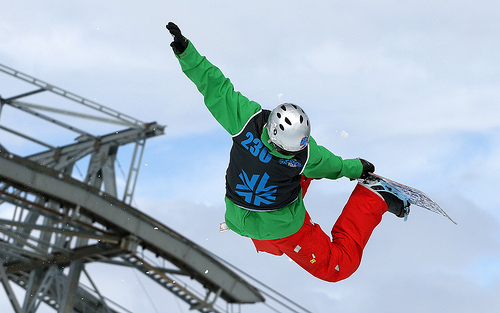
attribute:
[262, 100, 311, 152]
helmet — silver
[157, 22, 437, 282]
snowboarder — athletic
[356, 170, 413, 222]
boot — black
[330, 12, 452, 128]
cloud — white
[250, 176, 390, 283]
snow pants — red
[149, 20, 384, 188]
arms — out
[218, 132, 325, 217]
vest — black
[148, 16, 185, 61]
glove — black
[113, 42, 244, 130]
arm — outstreteched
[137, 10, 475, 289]
snow boarder — airborne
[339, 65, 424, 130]
clouds — white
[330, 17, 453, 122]
sky — blue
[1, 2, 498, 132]
clouds — white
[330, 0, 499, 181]
clouds — white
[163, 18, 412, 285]
person — athletic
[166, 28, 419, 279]
snowboarder — athletic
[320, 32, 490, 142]
clouds — white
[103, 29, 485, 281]
snowboarder — athletic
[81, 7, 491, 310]
sky — blue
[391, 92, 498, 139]
clouds — white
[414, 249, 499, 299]
clouds — white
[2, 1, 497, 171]
cloud — white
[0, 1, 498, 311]
sky — blue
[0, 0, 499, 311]
clouds — white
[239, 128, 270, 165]
number — blue, entry number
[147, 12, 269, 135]
arm — out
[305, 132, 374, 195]
arm — out